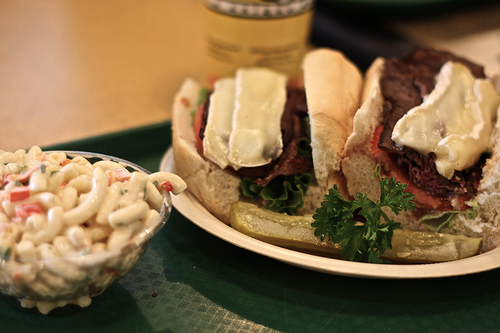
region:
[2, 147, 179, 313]
a small bowl of macaroni salad.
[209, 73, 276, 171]
it is either horseradish or mayonnaise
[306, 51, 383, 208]
part of a bread roll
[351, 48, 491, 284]
a roast beef sandwich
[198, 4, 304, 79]
a cup for soda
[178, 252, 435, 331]
a green plastic food tray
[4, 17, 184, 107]
part of a wooden table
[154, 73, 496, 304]
a plate filled with sandwiches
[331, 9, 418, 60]
a black purse strap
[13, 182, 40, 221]
sliced up tomatoes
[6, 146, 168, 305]
a bowl of macaroni salad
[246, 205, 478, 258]
a pickle slice covered with parsley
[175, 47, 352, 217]
a second roast beef sandwich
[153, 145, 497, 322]
the edge of a white dinner plate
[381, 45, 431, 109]
some roast beef to eat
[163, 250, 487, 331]
a green placemat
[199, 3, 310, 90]
a paper soda cup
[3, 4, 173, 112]
part of the wooden table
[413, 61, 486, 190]
something like mayo or horseradish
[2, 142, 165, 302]
macaroni salad on bowl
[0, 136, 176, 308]
creamy macaroni salad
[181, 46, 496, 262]
plate with sandwich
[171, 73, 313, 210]
sandwich with bread and cheese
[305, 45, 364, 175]
piece of white bread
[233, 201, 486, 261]
slice of pickle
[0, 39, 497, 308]
lunch with sandwich and macaroni salad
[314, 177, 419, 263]
piece of green parsley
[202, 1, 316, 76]
a carton of ice cream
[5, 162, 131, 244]
creamy macaroni salad with carrots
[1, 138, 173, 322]
Macaroni salad in bowl.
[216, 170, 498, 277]
Kosher pickle on plate.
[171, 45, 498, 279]
Kosher pickle beside sadwiches.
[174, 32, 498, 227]
Sandwiches on a bun.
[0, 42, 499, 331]
Food on a green tray.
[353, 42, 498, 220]
Mayonaisse on top of meat.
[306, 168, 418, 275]
Sprig of parsley for garnish.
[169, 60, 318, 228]
Lettuce on a sandwich.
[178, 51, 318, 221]
Tomatoes on top of lettuce.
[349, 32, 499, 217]
Meat has been browned.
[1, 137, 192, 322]
a bowl of pasta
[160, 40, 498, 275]
a full plate of food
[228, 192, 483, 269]
a slice of a pickle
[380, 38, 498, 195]
meat with cheese on top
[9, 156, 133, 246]
cooked elbow macaroni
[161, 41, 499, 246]
two sandwiches on a plate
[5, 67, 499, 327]
food on a green tray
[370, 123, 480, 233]
tomatoes on a sandwich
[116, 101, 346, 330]
a green tray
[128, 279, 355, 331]
a diamond shape design